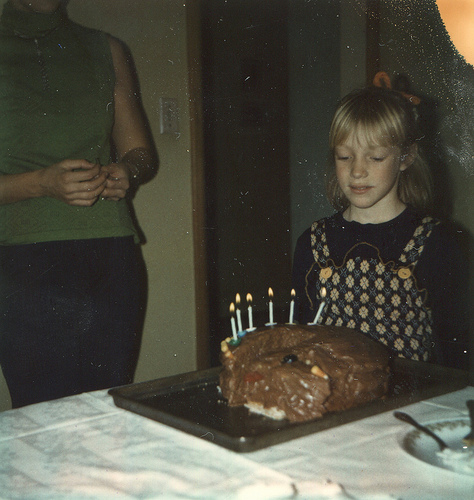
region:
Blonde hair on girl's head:
[325, 83, 440, 222]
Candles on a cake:
[214, 282, 333, 347]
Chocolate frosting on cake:
[214, 317, 396, 424]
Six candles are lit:
[222, 280, 332, 345]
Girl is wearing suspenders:
[285, 81, 471, 363]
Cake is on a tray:
[104, 315, 471, 455]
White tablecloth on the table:
[0, 382, 472, 498]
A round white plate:
[391, 413, 472, 479]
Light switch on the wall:
[153, 93, 181, 140]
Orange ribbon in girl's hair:
[365, 58, 426, 113]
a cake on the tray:
[158, 272, 364, 429]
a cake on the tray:
[204, 274, 445, 454]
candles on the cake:
[204, 264, 348, 358]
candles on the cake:
[181, 248, 384, 428]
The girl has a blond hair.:
[297, 85, 464, 361]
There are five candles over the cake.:
[228, 289, 294, 341]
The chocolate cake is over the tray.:
[224, 322, 390, 419]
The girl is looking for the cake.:
[295, 88, 466, 360]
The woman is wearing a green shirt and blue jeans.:
[0, 0, 159, 405]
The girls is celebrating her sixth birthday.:
[297, 83, 472, 359]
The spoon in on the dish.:
[396, 410, 452, 458]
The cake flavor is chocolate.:
[225, 321, 389, 419]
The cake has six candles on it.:
[223, 287, 390, 419]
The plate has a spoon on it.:
[399, 415, 472, 477]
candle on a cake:
[313, 282, 329, 323]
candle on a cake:
[282, 282, 308, 330]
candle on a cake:
[263, 284, 283, 335]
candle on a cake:
[244, 286, 262, 334]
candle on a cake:
[219, 299, 241, 351]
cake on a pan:
[187, 278, 401, 404]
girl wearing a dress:
[341, 74, 453, 329]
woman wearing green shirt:
[28, 8, 154, 372]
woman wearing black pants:
[15, 73, 145, 371]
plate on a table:
[388, 439, 434, 485]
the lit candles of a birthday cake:
[216, 269, 337, 344]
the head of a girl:
[321, 84, 426, 205]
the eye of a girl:
[332, 147, 352, 165]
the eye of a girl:
[368, 149, 389, 167]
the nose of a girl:
[349, 160, 375, 180]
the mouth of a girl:
[345, 181, 378, 198]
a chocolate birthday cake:
[214, 274, 408, 428]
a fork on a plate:
[387, 398, 464, 481]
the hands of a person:
[53, 151, 140, 213]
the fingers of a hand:
[74, 170, 106, 210]